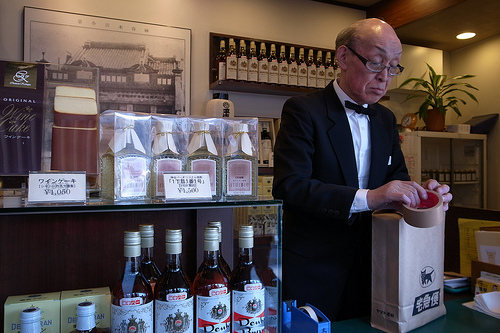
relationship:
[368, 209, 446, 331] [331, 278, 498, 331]
paper package on bar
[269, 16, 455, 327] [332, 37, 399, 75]
man wearing glasses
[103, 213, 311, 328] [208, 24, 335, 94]
bottles on shelf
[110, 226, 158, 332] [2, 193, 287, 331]
bottles on glass shelf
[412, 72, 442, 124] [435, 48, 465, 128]
plant that in corner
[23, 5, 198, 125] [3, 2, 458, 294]
framed picture on wall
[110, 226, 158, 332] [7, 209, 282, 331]
bottles on shelf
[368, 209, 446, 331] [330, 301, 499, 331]
paper package on bar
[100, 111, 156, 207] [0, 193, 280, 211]
bottle on glass shelf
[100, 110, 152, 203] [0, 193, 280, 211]
bottle on glass shelf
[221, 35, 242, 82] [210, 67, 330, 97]
bottle on shelf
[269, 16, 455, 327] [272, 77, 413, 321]
man wearing suit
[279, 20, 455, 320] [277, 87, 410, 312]
man dressed in suit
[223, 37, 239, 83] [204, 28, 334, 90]
bottle placed on a shelf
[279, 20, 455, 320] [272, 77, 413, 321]
man wearing suit